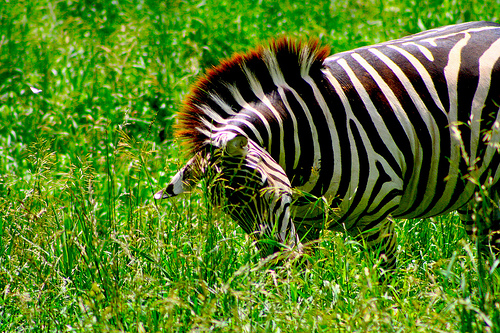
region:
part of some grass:
[180, 243, 217, 293]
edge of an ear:
[151, 172, 191, 205]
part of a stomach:
[391, 161, 453, 216]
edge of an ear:
[149, 186, 188, 211]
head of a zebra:
[206, 152, 243, 227]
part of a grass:
[136, 233, 203, 315]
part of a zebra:
[344, 159, 389, 232]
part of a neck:
[251, 88, 326, 143]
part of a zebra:
[205, 225, 257, 318]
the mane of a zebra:
[170, 31, 336, 156]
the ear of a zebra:
[217, 120, 252, 165]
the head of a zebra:
[148, 127, 314, 271]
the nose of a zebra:
[266, 245, 316, 285]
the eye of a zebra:
[256, 171, 274, 205]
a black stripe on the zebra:
[438, 27, 499, 219]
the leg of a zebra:
[363, 218, 413, 300]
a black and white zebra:
[147, 15, 499, 332]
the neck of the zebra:
[226, 102, 286, 169]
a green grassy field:
[0, 0, 499, 332]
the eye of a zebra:
[245, 155, 270, 185]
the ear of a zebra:
[150, 150, 206, 200]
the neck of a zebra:
[226, 99, 306, 164]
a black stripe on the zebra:
[228, 66, 284, 164]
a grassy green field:
[1, 2, 494, 332]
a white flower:
[23, 80, 52, 100]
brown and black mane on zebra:
[161, 26, 326, 124]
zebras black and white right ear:
[135, 149, 220, 212]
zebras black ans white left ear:
[216, 127, 248, 154]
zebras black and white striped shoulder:
[320, 120, 405, 257]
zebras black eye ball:
[248, 175, 283, 213]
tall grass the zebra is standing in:
[8, 50, 100, 292]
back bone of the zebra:
[268, 27, 484, 101]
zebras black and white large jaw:
[250, 141, 295, 230]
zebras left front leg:
[308, 214, 415, 294]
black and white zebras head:
[178, 93, 329, 328]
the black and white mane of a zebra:
[172, 38, 344, 134]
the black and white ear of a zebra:
[155, 158, 205, 191]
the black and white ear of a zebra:
[214, 129, 256, 155]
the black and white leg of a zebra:
[349, 214, 397, 272]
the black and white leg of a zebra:
[291, 214, 325, 255]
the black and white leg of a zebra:
[458, 199, 477, 241]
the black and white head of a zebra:
[207, 133, 310, 269]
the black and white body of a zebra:
[320, 15, 499, 223]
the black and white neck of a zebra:
[238, 76, 352, 226]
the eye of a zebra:
[260, 178, 271, 189]